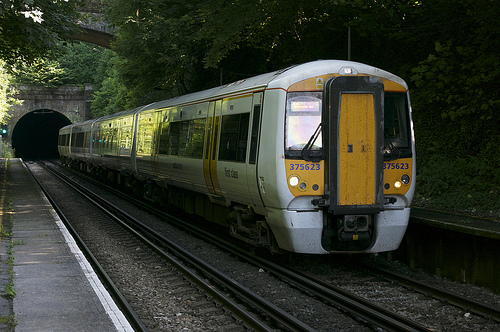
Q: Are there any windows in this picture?
A: Yes, there is a window.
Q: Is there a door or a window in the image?
A: Yes, there is a window.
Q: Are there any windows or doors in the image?
A: Yes, there is a window.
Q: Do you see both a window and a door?
A: Yes, there are both a window and a door.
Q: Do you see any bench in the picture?
A: No, there are no benches.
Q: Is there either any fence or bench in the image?
A: No, there are no benches or fences.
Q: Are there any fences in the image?
A: No, there are no fences.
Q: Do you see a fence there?
A: No, there are no fences.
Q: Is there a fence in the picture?
A: No, there are no fences.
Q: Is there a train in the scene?
A: Yes, there is a train.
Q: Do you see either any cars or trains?
A: Yes, there is a train.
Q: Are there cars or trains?
A: Yes, there is a train.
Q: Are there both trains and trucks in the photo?
A: No, there is a train but no trucks.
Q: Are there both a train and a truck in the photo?
A: No, there is a train but no trucks.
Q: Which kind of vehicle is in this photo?
A: The vehicle is a train.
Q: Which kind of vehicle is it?
A: The vehicle is a train.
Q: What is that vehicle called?
A: That is a train.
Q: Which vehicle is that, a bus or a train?
A: That is a train.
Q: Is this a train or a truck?
A: This is a train.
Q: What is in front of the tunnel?
A: The train is in front of the tunnel.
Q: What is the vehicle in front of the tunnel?
A: The vehicle is a train.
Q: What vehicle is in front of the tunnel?
A: The vehicle is a train.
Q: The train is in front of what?
A: The train is in front of the tunnel.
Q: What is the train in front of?
A: The train is in front of the tunnel.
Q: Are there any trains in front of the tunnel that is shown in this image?
A: Yes, there is a train in front of the tunnel.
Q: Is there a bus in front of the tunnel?
A: No, there is a train in front of the tunnel.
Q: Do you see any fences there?
A: No, there are no fences.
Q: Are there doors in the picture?
A: Yes, there is a door.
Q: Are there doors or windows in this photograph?
A: Yes, there is a door.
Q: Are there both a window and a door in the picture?
A: Yes, there are both a door and a window.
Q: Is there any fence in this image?
A: No, there are no fences.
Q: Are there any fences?
A: No, there are no fences.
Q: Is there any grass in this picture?
A: Yes, there is grass.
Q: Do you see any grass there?
A: Yes, there is grass.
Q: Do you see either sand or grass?
A: Yes, there is grass.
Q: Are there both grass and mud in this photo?
A: No, there is grass but no mud.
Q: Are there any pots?
A: No, there are no pots.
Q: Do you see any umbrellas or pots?
A: No, there are no pots or umbrellas.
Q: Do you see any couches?
A: No, there are no couches.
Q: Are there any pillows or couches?
A: No, there are no couches or pillows.